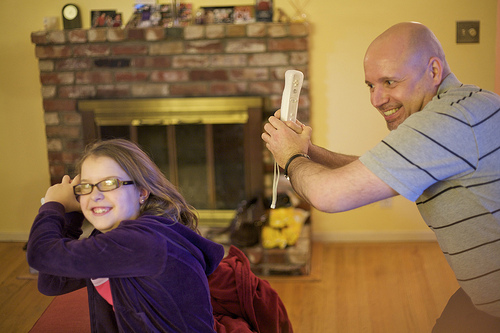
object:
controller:
[269, 68, 304, 208]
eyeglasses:
[71, 177, 143, 195]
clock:
[62, 3, 80, 30]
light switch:
[455, 19, 481, 42]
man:
[261, 21, 500, 333]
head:
[363, 19, 457, 131]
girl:
[28, 138, 225, 333]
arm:
[23, 170, 166, 278]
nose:
[371, 87, 391, 107]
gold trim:
[78, 96, 265, 233]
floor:
[0, 237, 499, 333]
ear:
[138, 182, 150, 204]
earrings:
[140, 198, 146, 201]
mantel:
[25, 18, 316, 71]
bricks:
[267, 35, 313, 56]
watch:
[284, 149, 310, 175]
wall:
[0, 0, 499, 243]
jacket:
[21, 198, 223, 333]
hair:
[74, 138, 204, 233]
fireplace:
[28, 23, 310, 273]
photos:
[86, 0, 278, 28]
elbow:
[299, 164, 346, 213]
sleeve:
[359, 101, 479, 200]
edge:
[360, 152, 419, 202]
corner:
[289, 17, 314, 41]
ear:
[429, 54, 443, 88]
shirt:
[358, 72, 500, 323]